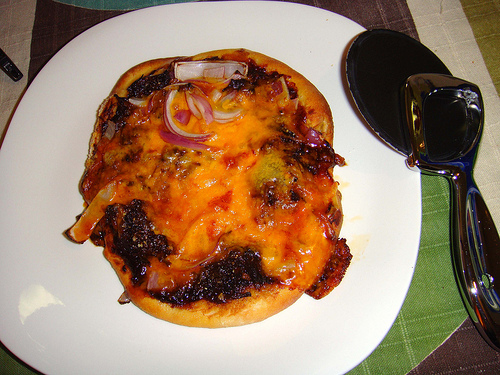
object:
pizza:
[60, 44, 355, 330]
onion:
[162, 97, 202, 139]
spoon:
[341, 28, 498, 343]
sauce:
[123, 103, 164, 160]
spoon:
[339, 21, 482, 276]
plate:
[0, 44, 117, 371]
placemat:
[412, 267, 465, 362]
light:
[451, 277, 491, 303]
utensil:
[338, 9, 496, 347]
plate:
[44, 289, 118, 370]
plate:
[10, 124, 70, 204]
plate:
[281, 318, 358, 373]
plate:
[144, 7, 203, 47]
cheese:
[114, 86, 331, 288]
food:
[67, 46, 354, 326]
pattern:
[422, 175, 499, 292]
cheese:
[163, 91, 343, 268]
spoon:
[351, 21, 486, 182]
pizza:
[173, 112, 252, 192]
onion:
[164, 89, 210, 141]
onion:
[184, 91, 198, 116]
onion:
[195, 86, 241, 118]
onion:
[195, 100, 207, 119]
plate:
[3, 0, 423, 374]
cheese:
[184, 169, 252, 244]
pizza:
[173, 50, 341, 351]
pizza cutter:
[333, 22, 500, 364]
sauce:
[277, 212, 312, 264]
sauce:
[69, 79, 334, 289]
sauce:
[222, 153, 240, 165]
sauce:
[280, 223, 302, 255]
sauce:
[89, 186, 129, 207]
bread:
[63, 49, 365, 327]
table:
[0, 3, 496, 369]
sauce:
[207, 185, 239, 221]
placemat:
[339, 170, 499, 371]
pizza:
[77, 39, 348, 340]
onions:
[162, 57, 246, 145]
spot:
[247, 148, 294, 199]